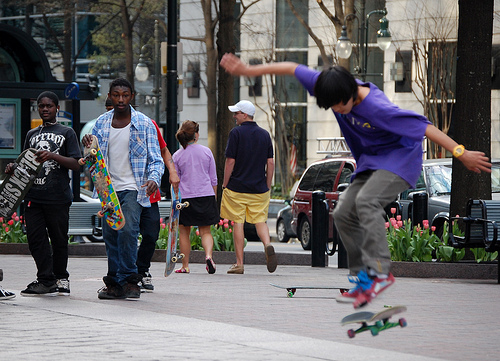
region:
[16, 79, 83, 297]
A person in the picture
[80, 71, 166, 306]
A person in the picture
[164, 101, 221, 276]
A person in the picture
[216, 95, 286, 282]
A person in the picture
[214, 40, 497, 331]
A person in the picture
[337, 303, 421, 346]
Skating board in the picture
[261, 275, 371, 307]
Skating board in the picture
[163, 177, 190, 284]
lSkating board in the picture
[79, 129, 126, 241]
Skating board in the picture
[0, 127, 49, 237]
Skating board in the picture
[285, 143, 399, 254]
The car is red.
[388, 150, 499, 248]
The car is silver.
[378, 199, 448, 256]
The flowers are pink.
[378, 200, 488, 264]
The flowers are in bloom.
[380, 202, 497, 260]
The flowers are leafy.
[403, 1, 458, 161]
The tree is bare.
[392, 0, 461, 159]
The tree is leafless.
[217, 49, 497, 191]
The boy's arms are outstretched.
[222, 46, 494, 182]
The boy is wearing a watch.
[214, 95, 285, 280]
The man is walking.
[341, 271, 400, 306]
red and white sneakers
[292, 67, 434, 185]
blue cotton tee shirt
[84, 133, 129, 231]
printed skate board in hand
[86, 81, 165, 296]
boy wearing plaid shirt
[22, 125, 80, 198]
black and white tee shirt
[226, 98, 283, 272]
man wearing yellow shorts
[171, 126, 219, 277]
girl wearing purple shirt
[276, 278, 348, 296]
skate board on side walk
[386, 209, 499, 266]
pink flowers next to side walk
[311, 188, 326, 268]
black metal pole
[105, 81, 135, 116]
astonished, admiring look on a person's face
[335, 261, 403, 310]
red trainers/sneakers/skate shoes, bright blue laces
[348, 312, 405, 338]
green metal board axles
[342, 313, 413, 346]
reddish wheels, at least two. greenish wheel, at least one.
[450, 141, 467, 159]
yellow watch or watchlike thing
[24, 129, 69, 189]
black t-shirt w/ white skull & a word i cannot read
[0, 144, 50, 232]
a skateboard whose underside reads, i think, 'black sheep' w/ a little schmutz, wear, & maybe a couple stickers on it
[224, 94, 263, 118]
bright white baseball cap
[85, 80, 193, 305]
dude almost entirely hidden behind other dude BUT whose skateboard & a smidge of red shirt+black pants are visible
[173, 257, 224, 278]
woman wearing very flat shoes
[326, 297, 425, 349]
skateboard with green and purple wheels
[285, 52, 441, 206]
purple tee shirt with yellow logo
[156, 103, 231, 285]
woman wearing pink shirt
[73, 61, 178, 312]
boy with colorful skateboard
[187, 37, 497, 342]
boy doing skateboard trick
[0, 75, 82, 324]
boy holding black skateboard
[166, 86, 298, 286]
man and woman walking together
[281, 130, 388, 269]
small red minivan on street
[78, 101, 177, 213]
blue plaid long sleeve shirt